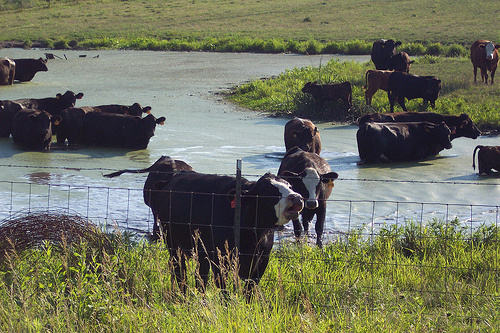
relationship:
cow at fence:
[130, 160, 321, 285] [6, 146, 477, 319]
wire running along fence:
[282, 185, 489, 316] [14, 163, 496, 276]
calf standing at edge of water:
[300, 81, 359, 112] [0, 49, 500, 232]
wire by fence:
[8, 203, 102, 312] [10, 173, 497, 270]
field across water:
[0, 1, 487, 53] [0, 49, 500, 232]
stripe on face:
[299, 159, 324, 201] [293, 163, 337, 215]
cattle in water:
[9, 107, 64, 153] [170, 110, 252, 149]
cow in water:
[351, 122, 454, 165] [82, 53, 219, 102]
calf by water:
[297, 79, 354, 103] [333, 159, 498, 224]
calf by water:
[297, 79, 354, 103] [113, 45, 278, 174]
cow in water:
[270, 145, 340, 247] [0, 49, 500, 232]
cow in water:
[145, 170, 304, 304] [0, 49, 500, 232]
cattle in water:
[281, 115, 323, 152] [0, 49, 500, 232]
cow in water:
[104, 152, 196, 239] [0, 49, 500, 232]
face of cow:
[266, 175, 304, 228] [261, 107, 336, 162]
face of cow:
[270, 177, 304, 227] [155, 156, 301, 298]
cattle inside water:
[281, 115, 323, 152] [0, 49, 500, 232]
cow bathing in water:
[359, 122, 454, 166] [360, 165, 452, 214]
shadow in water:
[246, 150, 366, 181] [0, 49, 500, 232]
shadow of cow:
[323, 141, 378, 176] [277, 100, 323, 160]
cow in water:
[351, 122, 454, 165] [2, 40, 499, 248]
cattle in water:
[280, 114, 320, 152] [2, 40, 499, 248]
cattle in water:
[72, 108, 168, 153] [2, 40, 499, 248]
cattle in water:
[16, 105, 61, 147] [2, 40, 499, 248]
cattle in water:
[10, 55, 47, 85] [2, 40, 499, 248]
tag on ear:
[228, 196, 239, 212] [228, 182, 249, 207]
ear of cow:
[228, 182, 249, 207] [249, 177, 301, 227]